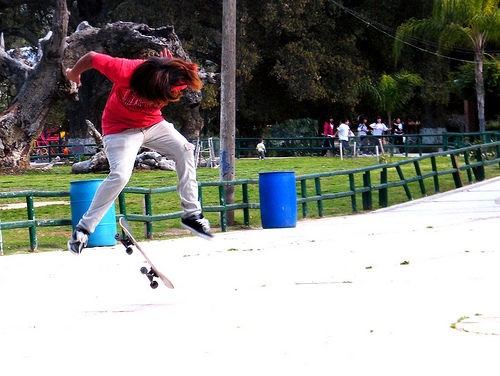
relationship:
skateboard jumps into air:
[120, 218, 175, 298] [141, 185, 175, 230]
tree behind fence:
[450, 1, 499, 137] [4, 157, 499, 243]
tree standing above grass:
[2, 5, 78, 174] [0, 175, 74, 191]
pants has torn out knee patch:
[69, 130, 209, 222] [182, 140, 199, 158]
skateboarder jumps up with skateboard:
[64, 46, 223, 259] [120, 218, 175, 298]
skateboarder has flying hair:
[64, 46, 223, 259] [133, 58, 203, 105]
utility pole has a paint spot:
[221, 4, 237, 223] [222, 148, 231, 177]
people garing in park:
[326, 114, 408, 156] [4, 3, 497, 232]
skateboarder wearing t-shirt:
[64, 46, 223, 259] [97, 57, 163, 123]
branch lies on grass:
[67, 121, 212, 171] [0, 175, 74, 191]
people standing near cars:
[326, 114, 408, 156] [272, 133, 372, 156]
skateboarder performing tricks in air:
[64, 46, 223, 259] [141, 185, 175, 230]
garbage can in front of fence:
[71, 182, 116, 246] [4, 157, 499, 243]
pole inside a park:
[221, 4, 237, 223] [4, 3, 497, 232]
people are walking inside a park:
[326, 114, 408, 156] [4, 3, 497, 232]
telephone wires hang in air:
[341, 19, 500, 58] [141, 185, 175, 230]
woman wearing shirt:
[323, 116, 338, 156] [324, 123, 335, 139]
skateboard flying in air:
[120, 218, 175, 298] [141, 185, 175, 230]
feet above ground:
[65, 228, 92, 257] [44, 270, 490, 367]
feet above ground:
[179, 214, 217, 242] [44, 270, 490, 367]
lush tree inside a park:
[450, 1, 499, 137] [4, 3, 497, 232]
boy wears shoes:
[64, 46, 223, 259] [65, 228, 92, 257]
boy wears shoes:
[64, 46, 223, 259] [179, 214, 217, 242]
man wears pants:
[64, 46, 223, 259] [69, 130, 209, 222]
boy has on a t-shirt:
[64, 46, 223, 259] [97, 57, 163, 123]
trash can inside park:
[71, 182, 116, 246] [4, 3, 497, 232]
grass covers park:
[0, 175, 74, 191] [4, 3, 497, 232]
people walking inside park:
[326, 114, 408, 156] [4, 3, 497, 232]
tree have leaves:
[256, 10, 364, 110] [278, 68, 290, 77]